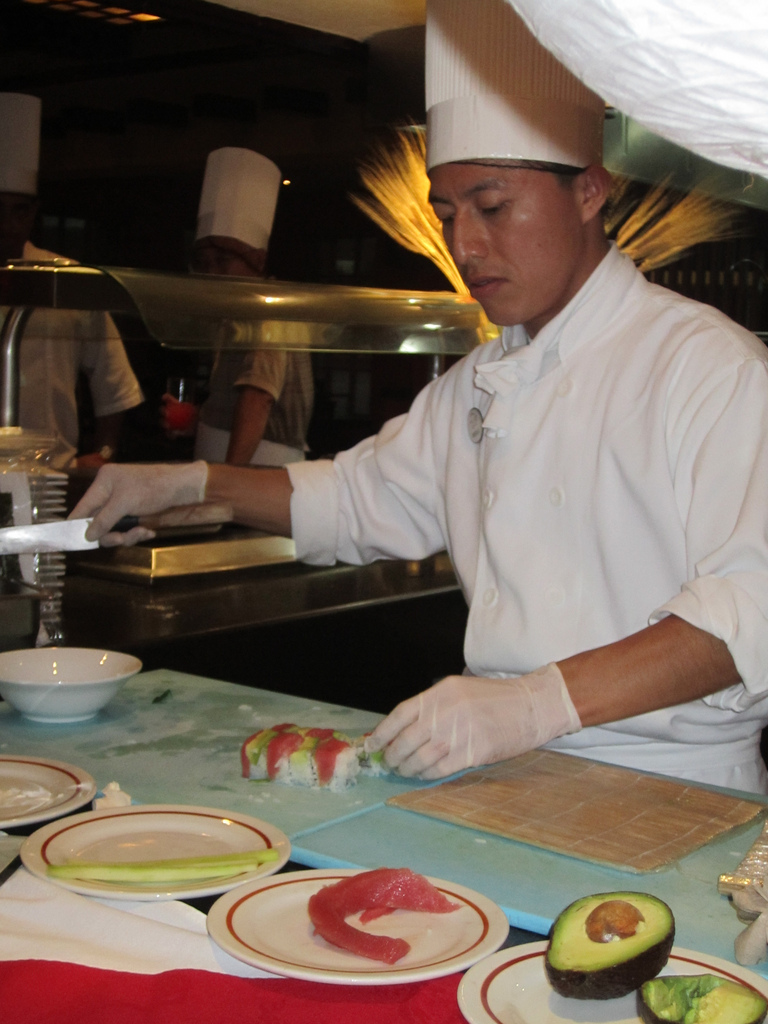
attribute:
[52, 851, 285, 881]
cucumber — sliced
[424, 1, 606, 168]
hat — tall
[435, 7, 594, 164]
hat — tall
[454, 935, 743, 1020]
plate — white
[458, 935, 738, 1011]
plate — white